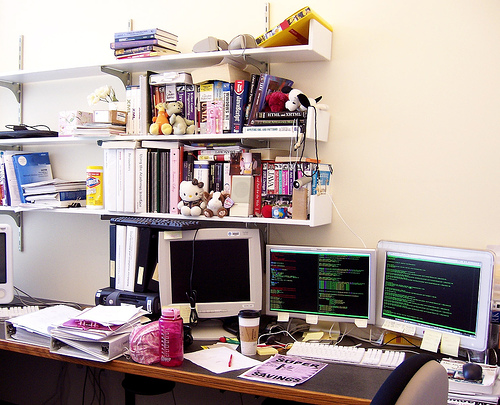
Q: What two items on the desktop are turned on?
A: Computer screens.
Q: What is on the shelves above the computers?
A: Books and small toys.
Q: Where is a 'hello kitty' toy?
A: On the shelf above the monitor that is not turned on.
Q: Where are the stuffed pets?
A: On shelves.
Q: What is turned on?
A: The computer screen.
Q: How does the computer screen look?
A: Turned on.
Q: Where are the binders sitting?
A: On a shelf.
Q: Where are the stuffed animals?
A: Shelf.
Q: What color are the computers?
A: White.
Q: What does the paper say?
A: Super savings.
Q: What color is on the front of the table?
A: Brown.